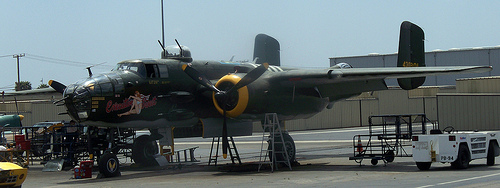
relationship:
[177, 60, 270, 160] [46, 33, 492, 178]
propeller of airplane